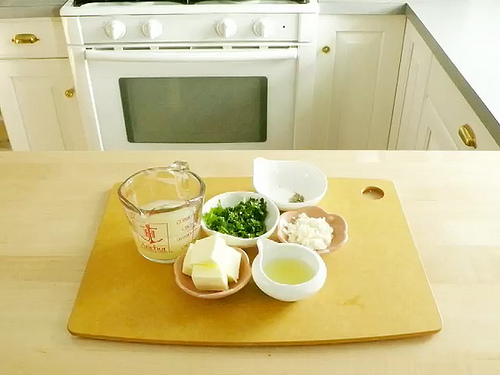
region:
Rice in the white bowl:
[290, 212, 335, 250]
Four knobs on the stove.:
[90, 14, 290, 53]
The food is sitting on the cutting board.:
[86, 155, 433, 361]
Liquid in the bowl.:
[271, 251, 302, 283]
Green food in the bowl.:
[214, 202, 269, 230]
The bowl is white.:
[261, 152, 324, 215]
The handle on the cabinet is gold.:
[449, 122, 474, 152]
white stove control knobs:
[101, 19, 278, 38]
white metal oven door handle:
[81, 43, 303, 69]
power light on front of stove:
[276, 18, 298, 39]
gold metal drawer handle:
[5, 26, 49, 51]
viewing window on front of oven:
[96, 63, 291, 149]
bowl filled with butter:
[174, 241, 251, 299]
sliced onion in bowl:
[276, 209, 353, 248]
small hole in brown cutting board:
[348, 182, 400, 204]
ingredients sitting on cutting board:
[109, 168, 371, 305]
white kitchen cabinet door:
[332, 20, 399, 144]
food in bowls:
[174, 157, 351, 303]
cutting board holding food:
[63, 169, 444, 351]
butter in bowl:
[171, 234, 251, 299]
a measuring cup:
[116, 157, 207, 267]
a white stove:
[58, 2, 320, 150]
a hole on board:
[362, 182, 388, 203]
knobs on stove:
[96, 17, 284, 42]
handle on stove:
[87, 48, 299, 63]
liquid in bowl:
[253, 242, 329, 303]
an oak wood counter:
[3, 149, 498, 374]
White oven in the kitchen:
[56, 0, 314, 150]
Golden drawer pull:
[7, 28, 48, 49]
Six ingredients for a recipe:
[50, 150, 460, 345]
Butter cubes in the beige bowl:
[176, 230, 248, 300]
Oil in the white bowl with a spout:
[247, 231, 327, 296]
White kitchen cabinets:
[0, 20, 95, 150]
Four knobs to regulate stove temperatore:
[75, 1, 287, 41]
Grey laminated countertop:
[322, 0, 494, 130]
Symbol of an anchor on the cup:
[132, 219, 169, 257]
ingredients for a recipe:
[81, 132, 408, 352]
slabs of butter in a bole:
[175, 230, 249, 310]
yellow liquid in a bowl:
[256, 232, 346, 332]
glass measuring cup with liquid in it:
[108, 150, 211, 276]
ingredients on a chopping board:
[79, 91, 452, 355]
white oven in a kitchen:
[52, 9, 367, 159]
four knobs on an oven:
[89, 13, 301, 58]